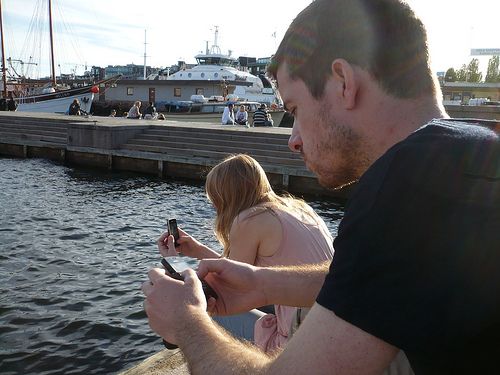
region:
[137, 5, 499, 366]
Man using cell phone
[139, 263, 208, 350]
Hand of man using phone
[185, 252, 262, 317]
Hand of man using phone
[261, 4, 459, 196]
Head of man using phone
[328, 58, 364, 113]
Ear of man using phone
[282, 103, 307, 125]
Eue of man using phone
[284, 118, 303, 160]
Nose of man using pone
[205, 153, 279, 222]
Head of woman using phone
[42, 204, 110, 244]
nice calm water near people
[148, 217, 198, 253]
Hands of woman using phone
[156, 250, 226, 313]
this guy is focused on his phone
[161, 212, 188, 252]
the young lady is focused on her phone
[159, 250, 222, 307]
the guy appears to be texting on his phone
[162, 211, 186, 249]
the young lady appears to be texting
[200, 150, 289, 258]
the young lady has blond hair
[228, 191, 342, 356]
the young lady is pretty in pink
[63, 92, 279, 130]
people in the distance sitting around talking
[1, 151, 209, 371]
the water is a little choppy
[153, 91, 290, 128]
a boat in the water in the background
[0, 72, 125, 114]
a sailboat in the distance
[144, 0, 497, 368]
a man and a woman on their cell phones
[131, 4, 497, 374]
a man and a woman by the water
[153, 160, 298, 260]
a woman looking at a cell phone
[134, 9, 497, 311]
a man looking at a cell phone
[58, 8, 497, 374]
people at a marina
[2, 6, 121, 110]
a ship in a marina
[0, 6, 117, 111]
a boat in a marina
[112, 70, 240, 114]
a building at a marina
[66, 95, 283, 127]
people sittin on a dock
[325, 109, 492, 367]
man wearing a t-shirt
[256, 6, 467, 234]
head of a person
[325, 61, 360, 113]
ear of a person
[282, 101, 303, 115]
eye of a person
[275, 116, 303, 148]
nose of a person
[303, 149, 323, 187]
mouth of a person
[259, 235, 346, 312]
arm of a person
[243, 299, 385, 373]
arm of a person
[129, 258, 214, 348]
hand of a person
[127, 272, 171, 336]
fingers of a person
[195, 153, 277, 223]
head of a person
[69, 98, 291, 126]
people sitting by a marina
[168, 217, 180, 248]
a cell phone in woman's hand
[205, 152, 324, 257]
woman with long blonde hair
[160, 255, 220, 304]
a black cell phone in man's hands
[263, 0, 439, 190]
man with short brown hair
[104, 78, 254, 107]
a on story building next to a marina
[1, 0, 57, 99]
two masts on a boat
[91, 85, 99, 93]
a red ball in the air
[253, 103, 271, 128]
person wearing a white and black stripe sweater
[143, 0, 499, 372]
a man and a woman sitting by the water